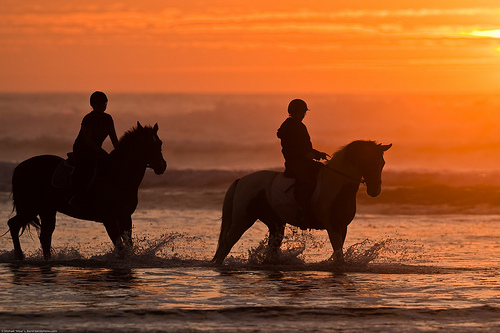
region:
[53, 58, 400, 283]
two horses in water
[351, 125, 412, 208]
head of the horse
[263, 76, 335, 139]
head of the person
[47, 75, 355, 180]
two people riding animals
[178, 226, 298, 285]
legs of the horse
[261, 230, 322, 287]
water splashing below horse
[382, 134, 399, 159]
ear of the horse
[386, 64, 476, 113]
sunset in the distance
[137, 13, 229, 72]
sky above the land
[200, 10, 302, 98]
clouds in the sky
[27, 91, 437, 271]
people are on horses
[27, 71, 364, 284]
horses are in water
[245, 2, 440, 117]
sky is dark orange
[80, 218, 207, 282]
horses splashing in water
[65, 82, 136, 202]
person sitting on horse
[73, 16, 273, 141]
few clouds in sky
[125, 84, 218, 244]
small waves in water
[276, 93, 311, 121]
person is wearing helmet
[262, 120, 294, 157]
person is wearing coat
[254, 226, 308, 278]
horse is kicking water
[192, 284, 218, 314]
the water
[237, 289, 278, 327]
the water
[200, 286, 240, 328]
the water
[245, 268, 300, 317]
the water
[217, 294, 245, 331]
the water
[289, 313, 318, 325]
the water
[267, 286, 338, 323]
the water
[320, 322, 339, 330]
the water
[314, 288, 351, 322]
the water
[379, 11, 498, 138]
orange sunset view visible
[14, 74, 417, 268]
People riding horses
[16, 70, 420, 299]
Horses are in the water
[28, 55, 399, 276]
The horses are walking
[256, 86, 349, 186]
The rider is wearing a helmet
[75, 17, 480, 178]
The sunset is orange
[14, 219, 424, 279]
The horses are splashing water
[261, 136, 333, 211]
The horse has a saddle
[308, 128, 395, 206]
The horse has a bridle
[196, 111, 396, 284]
The horse has spots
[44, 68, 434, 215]
There are waves behind the horses